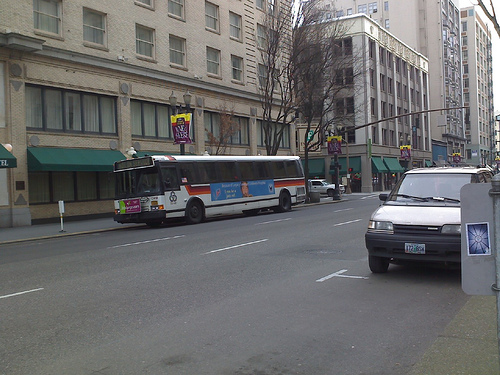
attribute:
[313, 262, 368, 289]
parking line — white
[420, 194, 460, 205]
wiper — black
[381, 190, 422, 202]
wiper — black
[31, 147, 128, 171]
awning — green